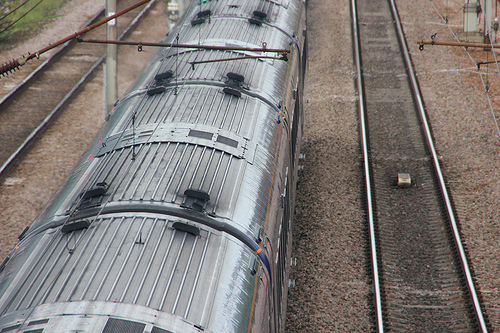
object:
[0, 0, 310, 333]
train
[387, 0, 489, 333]
tracks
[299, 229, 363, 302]
gravel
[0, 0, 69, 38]
grass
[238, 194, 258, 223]
sunlight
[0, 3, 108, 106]
tracks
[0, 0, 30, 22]
power line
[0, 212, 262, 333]
roof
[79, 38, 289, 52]
bar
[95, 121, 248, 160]
plate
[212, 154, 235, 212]
stripe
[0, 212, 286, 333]
car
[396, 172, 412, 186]
box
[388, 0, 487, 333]
rail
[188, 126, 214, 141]
vent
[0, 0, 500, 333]
ground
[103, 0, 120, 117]
pole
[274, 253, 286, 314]
window